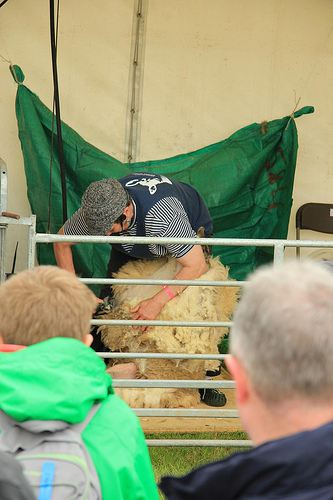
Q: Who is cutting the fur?
A: A man.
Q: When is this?
A: Daytime.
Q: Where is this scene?
A: Farm.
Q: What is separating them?
A: Gate.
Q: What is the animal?
A: Sheep.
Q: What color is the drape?
A: Greens.